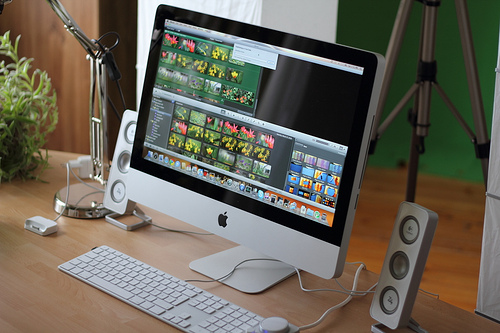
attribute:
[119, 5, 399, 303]
computer — black, apple, white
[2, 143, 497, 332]
desk — wooden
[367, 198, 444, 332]
speaker — small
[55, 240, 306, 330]
keyboard — white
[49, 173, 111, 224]
base — silver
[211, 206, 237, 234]
logo — black, apple, apple logo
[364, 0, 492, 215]
tripod — silver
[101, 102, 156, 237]
speaker — small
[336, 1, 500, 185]
wall — green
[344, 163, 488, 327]
floor — hardwood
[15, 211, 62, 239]
charger — small